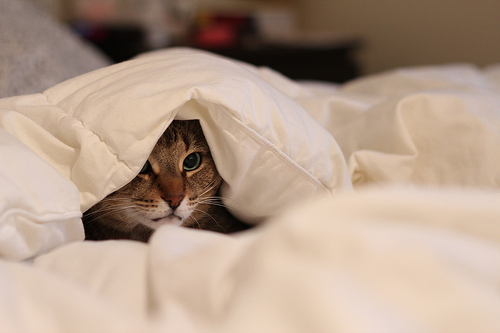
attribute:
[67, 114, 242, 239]
cat — brown, tabby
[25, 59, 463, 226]
blanket — fluffy, white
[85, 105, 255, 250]
cat — quiet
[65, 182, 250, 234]
whiskers — white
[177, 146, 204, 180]
eye — blue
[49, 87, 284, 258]
cat — attractive 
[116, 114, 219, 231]
cat — SWEET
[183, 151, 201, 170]
eye — green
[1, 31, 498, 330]
blanket — white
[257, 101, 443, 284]
blanket — white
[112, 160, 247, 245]
mouth — closed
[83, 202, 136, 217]
whisker — white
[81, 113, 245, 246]
cat — angry, cuddly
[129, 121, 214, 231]
cat — tan and black